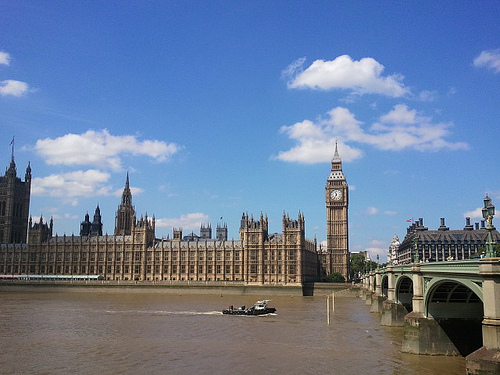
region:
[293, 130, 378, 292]
a huge clock tower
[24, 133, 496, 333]
perhaps this is London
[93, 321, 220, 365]
the water is very brown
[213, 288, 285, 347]
the boat is going to go under the bridge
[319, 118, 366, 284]
the clock reads 25 til 11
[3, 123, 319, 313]
all these buildings have points on the top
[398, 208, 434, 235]
a flag flies on this building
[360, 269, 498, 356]
the bridge has arches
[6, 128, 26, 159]
a flag flies at the top of this building as well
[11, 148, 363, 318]
all the buildings appear to be old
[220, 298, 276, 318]
A boat is on the river.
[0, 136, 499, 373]
The scene is of London.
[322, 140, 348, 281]
Big Ben is next to the river.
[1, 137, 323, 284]
The House of Parliament is next to the river.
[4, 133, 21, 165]
A flag is on the House of Parliament.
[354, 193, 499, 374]
A bridge crosses over the river.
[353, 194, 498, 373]
The bridge is green.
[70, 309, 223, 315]
The boat leaves a trail in the river.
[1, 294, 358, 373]
The river is brown.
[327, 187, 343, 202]
The clock of Big Ben reads 11:35.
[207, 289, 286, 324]
A vessel on the water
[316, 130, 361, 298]
Very big clock tower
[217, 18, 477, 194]
White puffy clouds above the tower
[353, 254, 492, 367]
Passeges under the bridge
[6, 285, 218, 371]
Water is muddy brown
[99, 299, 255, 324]
Boat leaves a wake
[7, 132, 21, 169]
Flag on top of tower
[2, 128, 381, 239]
Lots of towers on the structure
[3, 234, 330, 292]
The building has many windows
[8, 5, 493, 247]
Blue sky with just a few clouds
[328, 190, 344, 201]
white face of the clock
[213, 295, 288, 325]
a boat on the river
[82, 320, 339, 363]
brown water of the river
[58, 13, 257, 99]
clear blue skies over london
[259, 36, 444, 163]
sparse white clouds in the sky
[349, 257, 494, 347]
a green bridge crossing the river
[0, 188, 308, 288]
a brown gothic building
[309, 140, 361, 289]
a brown clock tower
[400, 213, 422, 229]
a flag being flown on top of a building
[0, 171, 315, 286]
British Parliament building in London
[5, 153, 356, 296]
government buildings are brown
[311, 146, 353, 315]
tall brown clock tower is on right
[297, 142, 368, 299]
tall clock tower is in London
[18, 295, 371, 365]
brown water on River Thames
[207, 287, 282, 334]
small dark colored boat on brown water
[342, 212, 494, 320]
bridge stretching across the river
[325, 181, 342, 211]
white face on clock tower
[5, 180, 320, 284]
brown building is used for governmental functions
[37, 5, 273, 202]
sky is blue with few clouds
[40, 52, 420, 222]
few clouds in sky are white and thin